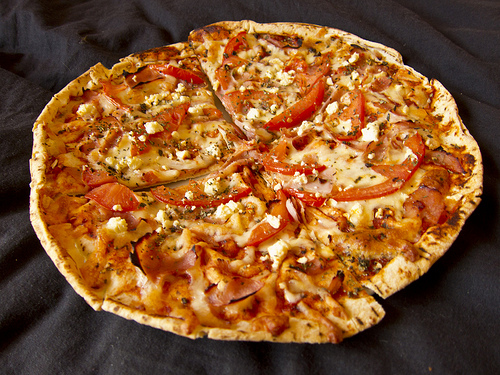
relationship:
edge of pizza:
[196, 14, 262, 39] [16, 14, 493, 352]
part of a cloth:
[427, 9, 479, 61] [470, 71, 499, 156]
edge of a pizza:
[196, 14, 262, 39] [16, 14, 493, 352]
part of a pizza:
[207, 22, 265, 73] [16, 14, 493, 352]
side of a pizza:
[78, 186, 311, 312] [16, 14, 493, 352]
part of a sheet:
[427, 9, 479, 61] [10, 8, 137, 46]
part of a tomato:
[207, 22, 265, 73] [163, 60, 208, 93]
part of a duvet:
[424, 281, 446, 308] [358, 335, 441, 360]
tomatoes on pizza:
[259, 75, 418, 210] [16, 14, 493, 352]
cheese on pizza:
[314, 150, 364, 184] [16, 14, 493, 352]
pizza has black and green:
[16, 14, 493, 352] [133, 127, 202, 159]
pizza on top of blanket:
[16, 14, 493, 352] [38, 3, 164, 17]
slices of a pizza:
[34, 41, 245, 204] [16, 14, 493, 352]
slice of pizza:
[189, 17, 397, 144] [16, 14, 493, 352]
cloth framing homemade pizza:
[470, 71, 499, 156] [16, 14, 493, 352]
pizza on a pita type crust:
[16, 14, 493, 352] [364, 262, 423, 287]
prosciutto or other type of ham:
[130, 231, 268, 314] [410, 174, 445, 221]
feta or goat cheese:
[142, 114, 165, 139] [109, 217, 133, 232]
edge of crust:
[196, 14, 262, 39] [364, 262, 423, 287]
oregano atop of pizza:
[342, 242, 375, 275] [16, 14, 493, 352]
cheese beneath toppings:
[314, 150, 364, 184] [254, 111, 389, 199]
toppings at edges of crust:
[254, 111, 389, 199] [364, 262, 423, 287]